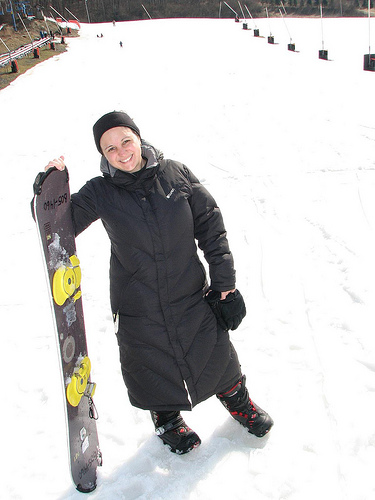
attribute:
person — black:
[30, 109, 272, 453]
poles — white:
[261, 11, 348, 64]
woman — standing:
[64, 108, 279, 464]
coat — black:
[30, 139, 236, 412]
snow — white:
[0, 18, 375, 497]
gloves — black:
[207, 286, 247, 329]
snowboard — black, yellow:
[29, 156, 106, 494]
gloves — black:
[210, 302, 244, 336]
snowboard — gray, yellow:
[34, 164, 109, 476]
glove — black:
[207, 286, 245, 331]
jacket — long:
[24, 150, 244, 412]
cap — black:
[81, 104, 141, 146]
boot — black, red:
[142, 361, 285, 457]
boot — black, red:
[146, 407, 202, 456]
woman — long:
[29, 104, 273, 452]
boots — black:
[229, 398, 281, 438]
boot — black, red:
[213, 375, 274, 439]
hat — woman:
[76, 96, 165, 163]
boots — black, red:
[124, 365, 272, 456]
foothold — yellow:
[45, 248, 100, 312]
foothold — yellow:
[49, 344, 113, 435]